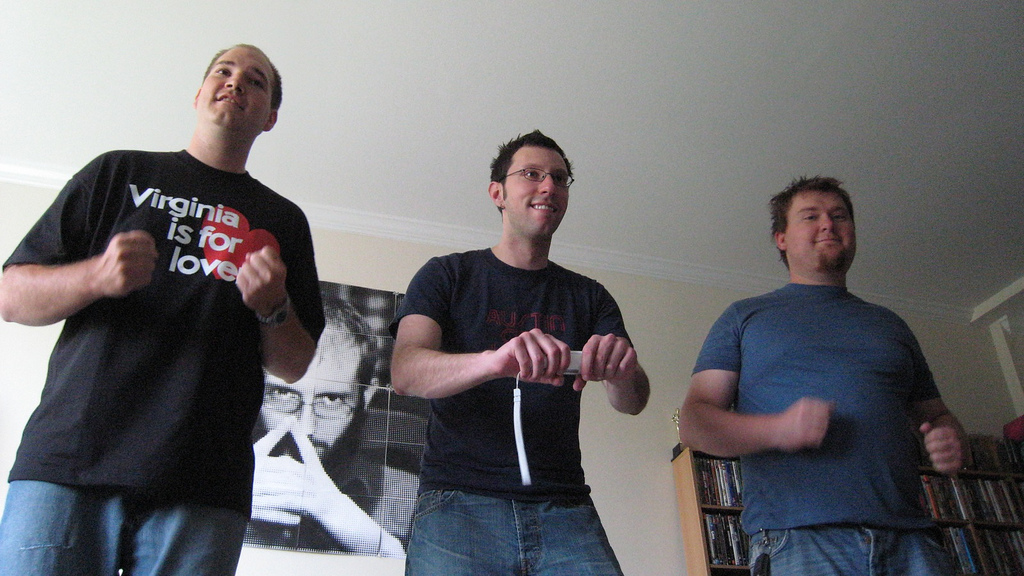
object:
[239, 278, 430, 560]
poster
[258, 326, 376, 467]
face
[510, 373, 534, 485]
strap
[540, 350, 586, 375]
wii remote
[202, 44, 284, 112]
hair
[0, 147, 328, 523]
shirt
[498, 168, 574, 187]
glasses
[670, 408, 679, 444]
award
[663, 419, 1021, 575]
bookcase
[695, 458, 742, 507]
dvd's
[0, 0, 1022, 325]
ceiling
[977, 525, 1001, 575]
movie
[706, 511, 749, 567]
movie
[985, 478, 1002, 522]
movie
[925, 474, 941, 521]
movie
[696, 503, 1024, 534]
shelf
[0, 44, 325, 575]
men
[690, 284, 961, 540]
shirt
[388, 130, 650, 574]
man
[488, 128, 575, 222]
dark hair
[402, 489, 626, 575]
blue jeans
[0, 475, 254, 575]
blue jeans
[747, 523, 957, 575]
blue jeans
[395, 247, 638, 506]
shirt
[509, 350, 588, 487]
remote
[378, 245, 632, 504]
man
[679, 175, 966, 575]
man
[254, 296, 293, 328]
watch